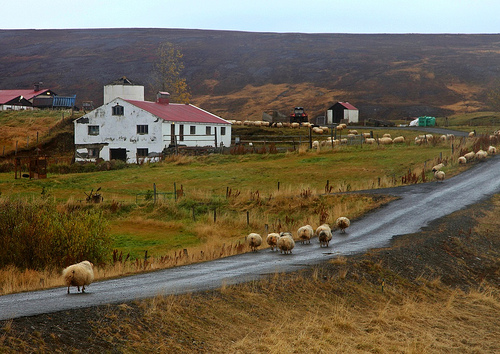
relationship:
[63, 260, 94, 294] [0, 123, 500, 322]
sheep on road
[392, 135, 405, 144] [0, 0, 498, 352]
sheep in field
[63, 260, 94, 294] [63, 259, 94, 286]
sheep has wool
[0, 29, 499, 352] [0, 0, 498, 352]
grass on field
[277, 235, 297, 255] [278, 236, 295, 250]
sheep has wool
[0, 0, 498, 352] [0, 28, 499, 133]
field has hill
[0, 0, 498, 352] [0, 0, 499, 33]
field under sky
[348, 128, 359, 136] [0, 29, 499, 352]
sheep on grass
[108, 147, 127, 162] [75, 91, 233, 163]
doorway in barn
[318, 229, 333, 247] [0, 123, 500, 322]
sheep on road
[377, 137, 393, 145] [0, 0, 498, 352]
sheep in field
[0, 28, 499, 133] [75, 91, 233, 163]
hill behind barn